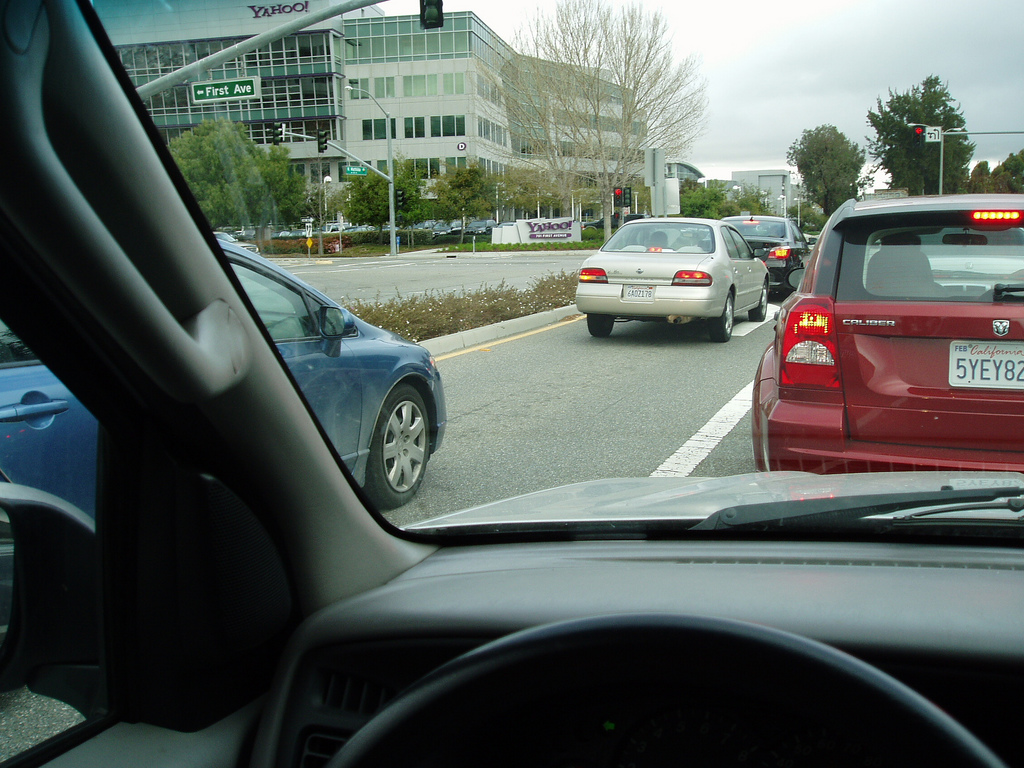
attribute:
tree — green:
[994, 145, 1021, 199]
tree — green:
[971, 160, 998, 192]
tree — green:
[675, 170, 714, 227]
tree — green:
[343, 174, 395, 242]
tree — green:
[503, 163, 558, 221]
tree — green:
[453, 165, 495, 239]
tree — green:
[169, 123, 245, 234]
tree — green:
[220, 117, 277, 260]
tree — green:
[729, 182, 771, 231]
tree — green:
[725, 176, 779, 234]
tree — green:
[482, 161, 509, 235]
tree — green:
[789, 190, 816, 241]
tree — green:
[994, 157, 1021, 200]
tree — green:
[680, 183, 709, 221]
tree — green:
[396, 158, 431, 245]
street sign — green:
[190, 71, 279, 106]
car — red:
[568, 208, 773, 347]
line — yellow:
[428, 311, 587, 363]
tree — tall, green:
[860, 64, 978, 189]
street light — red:
[899, 117, 948, 144]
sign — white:
[515, 215, 593, 251]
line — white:
[649, 383, 752, 476]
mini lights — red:
[972, 207, 1021, 224]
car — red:
[743, 183, 1022, 484]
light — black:
[417, 0, 453, 26]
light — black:
[906, 112, 926, 155]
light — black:
[610, 181, 633, 207]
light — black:
[312, 123, 328, 152]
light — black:
[265, 114, 284, 147]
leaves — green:
[671, 177, 742, 222]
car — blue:
[21, 196, 470, 526]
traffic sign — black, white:
[904, 120, 942, 143]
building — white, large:
[84, 4, 654, 229]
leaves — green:
[796, 129, 864, 209]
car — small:
[573, 196, 766, 343]